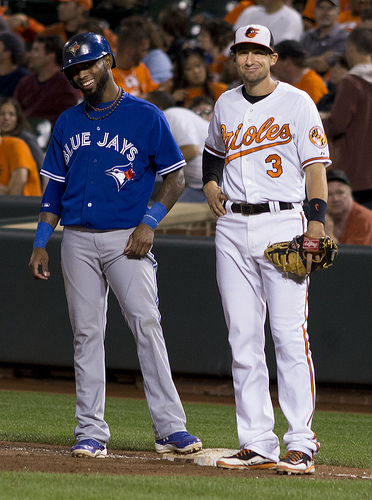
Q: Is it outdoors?
A: Yes, it is outdoors.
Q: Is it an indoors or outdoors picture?
A: It is outdoors.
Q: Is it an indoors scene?
A: No, it is outdoors.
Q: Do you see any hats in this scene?
A: Yes, there is a hat.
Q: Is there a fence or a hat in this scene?
A: Yes, there is a hat.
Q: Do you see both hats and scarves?
A: No, there is a hat but no scarves.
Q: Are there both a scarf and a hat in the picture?
A: No, there is a hat but no scarves.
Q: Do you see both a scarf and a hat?
A: No, there is a hat but no scarves.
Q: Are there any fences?
A: No, there are no fences.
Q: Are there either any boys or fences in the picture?
A: No, there are no fences or boys.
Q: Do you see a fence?
A: No, there are no fences.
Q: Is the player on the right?
A: Yes, the player is on the right of the image.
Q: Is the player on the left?
A: No, the player is on the right of the image.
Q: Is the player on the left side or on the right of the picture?
A: The player is on the right of the image.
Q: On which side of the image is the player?
A: The player is on the right of the image.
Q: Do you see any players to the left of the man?
A: Yes, there is a player to the left of the man.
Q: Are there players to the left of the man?
A: Yes, there is a player to the left of the man.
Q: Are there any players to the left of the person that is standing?
A: Yes, there is a player to the left of the man.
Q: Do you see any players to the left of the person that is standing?
A: Yes, there is a player to the left of the man.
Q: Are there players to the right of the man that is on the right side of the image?
A: No, the player is to the left of the man.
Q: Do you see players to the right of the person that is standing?
A: No, the player is to the left of the man.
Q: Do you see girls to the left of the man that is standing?
A: No, there is a player to the left of the man.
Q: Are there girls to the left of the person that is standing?
A: No, there is a player to the left of the man.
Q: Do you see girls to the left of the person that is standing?
A: No, there is a player to the left of the man.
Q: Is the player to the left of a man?
A: Yes, the player is to the left of a man.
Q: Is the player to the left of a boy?
A: No, the player is to the left of a man.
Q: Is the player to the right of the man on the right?
A: No, the player is to the left of the man.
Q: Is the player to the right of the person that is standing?
A: No, the player is to the left of the man.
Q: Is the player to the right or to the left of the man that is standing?
A: The player is to the left of the man.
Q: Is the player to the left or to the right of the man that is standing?
A: The player is to the left of the man.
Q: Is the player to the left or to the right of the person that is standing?
A: The player is to the left of the man.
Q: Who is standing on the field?
A: The player is standing on the field.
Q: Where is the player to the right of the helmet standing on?
A: The player is standing on the field.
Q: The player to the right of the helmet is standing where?
A: The player is standing on the field.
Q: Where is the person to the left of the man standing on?
A: The player is standing on the field.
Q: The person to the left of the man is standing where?
A: The player is standing on the field.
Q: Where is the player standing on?
A: The player is standing on the field.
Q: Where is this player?
A: The player is on the field.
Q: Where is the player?
A: The player is on the field.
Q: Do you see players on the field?
A: Yes, there is a player on the field.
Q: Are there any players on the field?
A: Yes, there is a player on the field.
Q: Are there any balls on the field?
A: No, there is a player on the field.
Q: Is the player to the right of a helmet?
A: Yes, the player is to the right of a helmet.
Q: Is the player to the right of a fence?
A: No, the player is to the right of a helmet.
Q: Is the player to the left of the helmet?
A: No, the player is to the right of the helmet.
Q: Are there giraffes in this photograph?
A: No, there are no giraffes.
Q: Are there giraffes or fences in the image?
A: No, there are no giraffes or fences.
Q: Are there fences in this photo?
A: No, there are no fences.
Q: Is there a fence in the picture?
A: No, there are no fences.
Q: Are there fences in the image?
A: No, there are no fences.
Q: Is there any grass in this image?
A: Yes, there is grass.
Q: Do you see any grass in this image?
A: Yes, there is grass.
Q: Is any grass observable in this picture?
A: Yes, there is grass.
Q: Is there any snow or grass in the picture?
A: Yes, there is grass.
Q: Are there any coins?
A: No, there are no coins.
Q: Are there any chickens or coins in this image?
A: No, there are no coins or chickens.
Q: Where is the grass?
A: The grass is on the field.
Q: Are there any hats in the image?
A: Yes, there is a hat.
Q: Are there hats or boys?
A: Yes, there is a hat.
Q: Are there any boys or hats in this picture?
A: Yes, there is a hat.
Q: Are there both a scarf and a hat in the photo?
A: No, there is a hat but no scarves.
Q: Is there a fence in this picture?
A: No, there are no fences.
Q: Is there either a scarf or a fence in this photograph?
A: No, there are no fences or scarves.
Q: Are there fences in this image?
A: No, there are no fences.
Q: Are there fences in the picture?
A: No, there are no fences.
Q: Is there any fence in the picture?
A: No, there are no fences.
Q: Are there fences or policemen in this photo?
A: No, there are no fences or policemen.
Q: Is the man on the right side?
A: Yes, the man is on the right of the image.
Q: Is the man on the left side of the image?
A: No, the man is on the right of the image.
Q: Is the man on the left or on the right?
A: The man is on the right of the image.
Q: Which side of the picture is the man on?
A: The man is on the right of the image.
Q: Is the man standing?
A: Yes, the man is standing.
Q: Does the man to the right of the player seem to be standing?
A: Yes, the man is standing.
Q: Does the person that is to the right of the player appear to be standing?
A: Yes, the man is standing.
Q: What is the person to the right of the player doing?
A: The man is standing.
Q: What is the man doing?
A: The man is standing.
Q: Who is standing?
A: The man is standing.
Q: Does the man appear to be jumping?
A: No, the man is standing.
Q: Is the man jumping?
A: No, the man is standing.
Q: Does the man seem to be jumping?
A: No, the man is standing.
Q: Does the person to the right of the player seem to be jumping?
A: No, the man is standing.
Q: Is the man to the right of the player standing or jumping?
A: The man is standing.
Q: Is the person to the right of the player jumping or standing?
A: The man is standing.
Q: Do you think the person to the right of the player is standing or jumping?
A: The man is standing.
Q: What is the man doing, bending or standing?
A: The man is standing.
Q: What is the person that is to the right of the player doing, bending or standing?
A: The man is standing.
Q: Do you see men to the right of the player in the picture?
A: Yes, there is a man to the right of the player.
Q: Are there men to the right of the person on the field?
A: Yes, there is a man to the right of the player.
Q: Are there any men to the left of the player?
A: No, the man is to the right of the player.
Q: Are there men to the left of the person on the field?
A: No, the man is to the right of the player.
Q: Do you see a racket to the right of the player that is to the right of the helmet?
A: No, there is a man to the right of the player.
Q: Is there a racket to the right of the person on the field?
A: No, there is a man to the right of the player.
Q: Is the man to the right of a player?
A: Yes, the man is to the right of a player.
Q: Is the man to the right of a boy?
A: No, the man is to the right of a player.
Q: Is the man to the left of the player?
A: No, the man is to the right of the player.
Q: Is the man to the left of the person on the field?
A: No, the man is to the right of the player.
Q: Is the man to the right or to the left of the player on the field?
A: The man is to the right of the player.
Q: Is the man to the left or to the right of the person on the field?
A: The man is to the right of the player.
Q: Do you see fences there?
A: No, there are no fences.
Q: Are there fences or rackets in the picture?
A: No, there are no fences or rackets.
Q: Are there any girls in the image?
A: No, there are no girls.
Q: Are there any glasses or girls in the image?
A: No, there are no girls or glasses.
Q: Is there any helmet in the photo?
A: Yes, there is a helmet.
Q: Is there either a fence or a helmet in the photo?
A: Yes, there is a helmet.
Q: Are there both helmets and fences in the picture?
A: No, there is a helmet but no fences.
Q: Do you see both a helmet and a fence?
A: No, there is a helmet but no fences.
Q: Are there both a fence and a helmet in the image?
A: No, there is a helmet but no fences.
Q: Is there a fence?
A: No, there are no fences.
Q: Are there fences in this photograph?
A: No, there are no fences.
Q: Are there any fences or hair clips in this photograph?
A: No, there are no fences or hair clips.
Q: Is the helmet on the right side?
A: No, the helmet is on the left of the image.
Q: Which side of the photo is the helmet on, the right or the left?
A: The helmet is on the left of the image.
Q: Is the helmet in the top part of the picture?
A: Yes, the helmet is in the top of the image.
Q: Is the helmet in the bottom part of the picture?
A: No, the helmet is in the top of the image.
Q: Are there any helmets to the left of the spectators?
A: Yes, there is a helmet to the left of the spectators.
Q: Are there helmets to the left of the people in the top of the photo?
A: Yes, there is a helmet to the left of the spectators.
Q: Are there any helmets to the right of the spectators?
A: No, the helmet is to the left of the spectators.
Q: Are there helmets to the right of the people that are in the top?
A: No, the helmet is to the left of the spectators.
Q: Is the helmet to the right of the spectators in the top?
A: No, the helmet is to the left of the spectators.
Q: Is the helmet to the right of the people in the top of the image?
A: No, the helmet is to the left of the spectators.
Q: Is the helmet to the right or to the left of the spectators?
A: The helmet is to the left of the spectators.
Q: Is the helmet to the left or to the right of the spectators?
A: The helmet is to the left of the spectators.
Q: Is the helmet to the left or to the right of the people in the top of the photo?
A: The helmet is to the left of the spectators.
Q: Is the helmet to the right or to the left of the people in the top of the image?
A: The helmet is to the left of the spectators.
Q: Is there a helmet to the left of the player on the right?
A: Yes, there is a helmet to the left of the player.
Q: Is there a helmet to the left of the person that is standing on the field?
A: Yes, there is a helmet to the left of the player.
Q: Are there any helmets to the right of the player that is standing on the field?
A: No, the helmet is to the left of the player.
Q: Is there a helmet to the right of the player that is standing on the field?
A: No, the helmet is to the left of the player.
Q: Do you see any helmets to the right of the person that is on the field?
A: No, the helmet is to the left of the player.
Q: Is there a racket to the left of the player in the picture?
A: No, there is a helmet to the left of the player.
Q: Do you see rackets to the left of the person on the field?
A: No, there is a helmet to the left of the player.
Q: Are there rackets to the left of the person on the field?
A: No, there is a helmet to the left of the player.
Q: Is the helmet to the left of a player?
A: Yes, the helmet is to the left of a player.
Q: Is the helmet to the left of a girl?
A: No, the helmet is to the left of a player.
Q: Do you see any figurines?
A: No, there are no figurines.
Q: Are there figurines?
A: No, there are no figurines.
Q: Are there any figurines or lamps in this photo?
A: No, there are no figurines or lamps.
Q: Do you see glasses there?
A: No, there are no glasses.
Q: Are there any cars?
A: No, there are no cars.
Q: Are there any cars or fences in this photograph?
A: No, there are no cars or fences.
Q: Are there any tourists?
A: No, there are no tourists.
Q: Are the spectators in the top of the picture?
A: Yes, the spectators are in the top of the image.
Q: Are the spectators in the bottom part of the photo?
A: No, the spectators are in the top of the image.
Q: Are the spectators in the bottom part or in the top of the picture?
A: The spectators are in the top of the image.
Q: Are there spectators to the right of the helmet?
A: Yes, there are spectators to the right of the helmet.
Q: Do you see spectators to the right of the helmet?
A: Yes, there are spectators to the right of the helmet.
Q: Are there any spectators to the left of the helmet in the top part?
A: No, the spectators are to the right of the helmet.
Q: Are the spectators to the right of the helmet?
A: Yes, the spectators are to the right of the helmet.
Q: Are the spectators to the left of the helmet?
A: No, the spectators are to the right of the helmet.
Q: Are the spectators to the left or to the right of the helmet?
A: The spectators are to the right of the helmet.